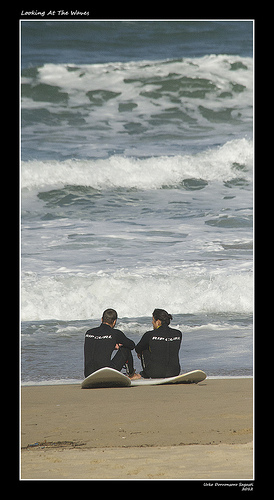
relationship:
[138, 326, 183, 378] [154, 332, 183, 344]
wetsuit has white text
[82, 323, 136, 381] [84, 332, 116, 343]
wetsuit has white text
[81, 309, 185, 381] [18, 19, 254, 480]
people in a picture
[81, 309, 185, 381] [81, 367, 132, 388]
people on their surfboard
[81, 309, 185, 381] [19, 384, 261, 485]
people are on beach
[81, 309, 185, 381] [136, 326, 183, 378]
people have wetsuit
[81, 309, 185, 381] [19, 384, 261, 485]
people on beach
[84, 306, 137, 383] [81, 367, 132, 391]
person on a surfboard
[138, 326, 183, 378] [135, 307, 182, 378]
wetsuit on a people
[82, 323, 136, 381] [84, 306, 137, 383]
wetsuit on a man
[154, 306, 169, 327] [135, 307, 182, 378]
hair on people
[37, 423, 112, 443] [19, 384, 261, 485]
sand on beach